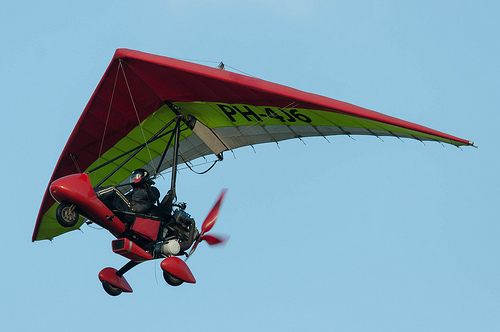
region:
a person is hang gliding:
[38, 33, 482, 298]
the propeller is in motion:
[180, 179, 259, 274]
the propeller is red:
[171, 171, 237, 261]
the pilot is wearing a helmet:
[110, 151, 161, 206]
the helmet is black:
[117, 165, 164, 189]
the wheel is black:
[35, 189, 87, 234]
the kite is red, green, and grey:
[19, 36, 485, 175]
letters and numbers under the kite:
[199, 85, 320, 130]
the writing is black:
[200, 93, 319, 130]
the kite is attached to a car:
[15, 36, 473, 281]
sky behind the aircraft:
[300, 166, 355, 256]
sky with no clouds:
[296, 200, 365, 256]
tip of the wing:
[433, 110, 490, 187]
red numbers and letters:
[214, 98, 309, 138]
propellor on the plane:
[190, 192, 237, 262]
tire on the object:
[51, 185, 83, 236]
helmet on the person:
[116, 155, 156, 197]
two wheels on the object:
[110, 250, 195, 300]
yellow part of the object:
[201, 97, 226, 134]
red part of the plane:
[103, 53, 170, 90]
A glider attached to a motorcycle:
[29, 41, 459, 308]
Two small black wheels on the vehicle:
[103, 270, 203, 305]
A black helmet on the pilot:
[127, 166, 157, 186]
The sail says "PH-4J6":
[221, 94, 322, 134]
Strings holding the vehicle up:
[98, 60, 165, 190]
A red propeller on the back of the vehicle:
[193, 199, 234, 261]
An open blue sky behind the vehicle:
[252, 200, 439, 325]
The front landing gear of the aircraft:
[54, 199, 84, 229]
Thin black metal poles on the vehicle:
[114, 123, 184, 198]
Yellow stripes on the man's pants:
[99, 185, 131, 207]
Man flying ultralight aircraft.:
[26, 27, 488, 319]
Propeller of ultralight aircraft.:
[186, 181, 243, 258]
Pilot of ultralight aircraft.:
[118, 150, 169, 229]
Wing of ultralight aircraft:
[66, 37, 483, 162]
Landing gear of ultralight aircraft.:
[94, 258, 219, 298]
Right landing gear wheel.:
[159, 254, 206, 296]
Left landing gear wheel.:
[88, 262, 140, 306]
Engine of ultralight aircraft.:
[168, 200, 202, 257]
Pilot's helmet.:
[130, 163, 159, 186]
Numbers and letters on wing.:
[216, 96, 313, 141]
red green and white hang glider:
[30, 48, 473, 245]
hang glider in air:
[33, 50, 470, 245]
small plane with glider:
[48, 173, 225, 295]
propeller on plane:
[192, 189, 228, 256]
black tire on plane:
[56, 201, 79, 228]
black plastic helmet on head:
[128, 168, 149, 182]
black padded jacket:
[124, 183, 161, 210]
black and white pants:
[93, 185, 132, 209]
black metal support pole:
[171, 123, 178, 200]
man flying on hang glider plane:
[98, 168, 161, 215]